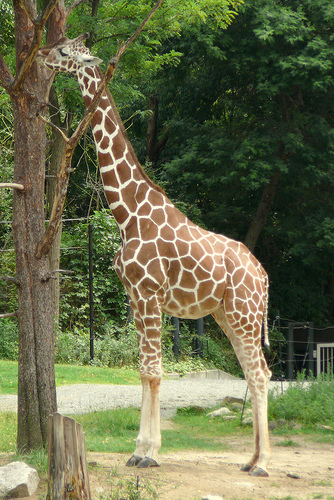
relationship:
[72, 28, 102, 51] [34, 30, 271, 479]
ossicone on giraffe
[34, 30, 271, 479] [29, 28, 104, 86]
giraffe has head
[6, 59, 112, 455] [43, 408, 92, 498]
tree has stump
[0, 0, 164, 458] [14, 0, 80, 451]
tree has bark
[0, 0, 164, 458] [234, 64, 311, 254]
tree has branch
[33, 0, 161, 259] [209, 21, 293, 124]
branch of tree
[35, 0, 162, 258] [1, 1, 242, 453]
branch of tree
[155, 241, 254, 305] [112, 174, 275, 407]
spots on fur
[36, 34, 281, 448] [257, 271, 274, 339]
giraffe with tail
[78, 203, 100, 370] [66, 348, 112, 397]
pole in ground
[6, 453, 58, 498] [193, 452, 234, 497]
rock on ground